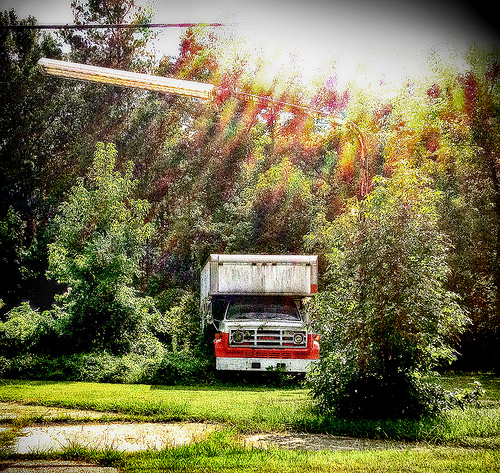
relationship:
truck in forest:
[177, 235, 374, 435] [12, 10, 471, 432]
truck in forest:
[198, 253, 320, 386] [1, 3, 498, 409]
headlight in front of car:
[293, 331, 304, 344] [191, 255, 326, 372]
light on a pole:
[36, 54, 214, 103] [230, 79, 368, 391]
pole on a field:
[35, 57, 385, 435] [3, 370, 498, 471]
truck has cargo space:
[195, 249, 322, 383] [205, 245, 317, 301]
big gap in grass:
[18, 414, 218, 446] [17, 381, 307, 431]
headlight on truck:
[224, 330, 305, 347] [198, 253, 320, 386]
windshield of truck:
[223, 296, 301, 322] [198, 253, 320, 386]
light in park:
[36, 54, 214, 103] [3, 0, 494, 472]